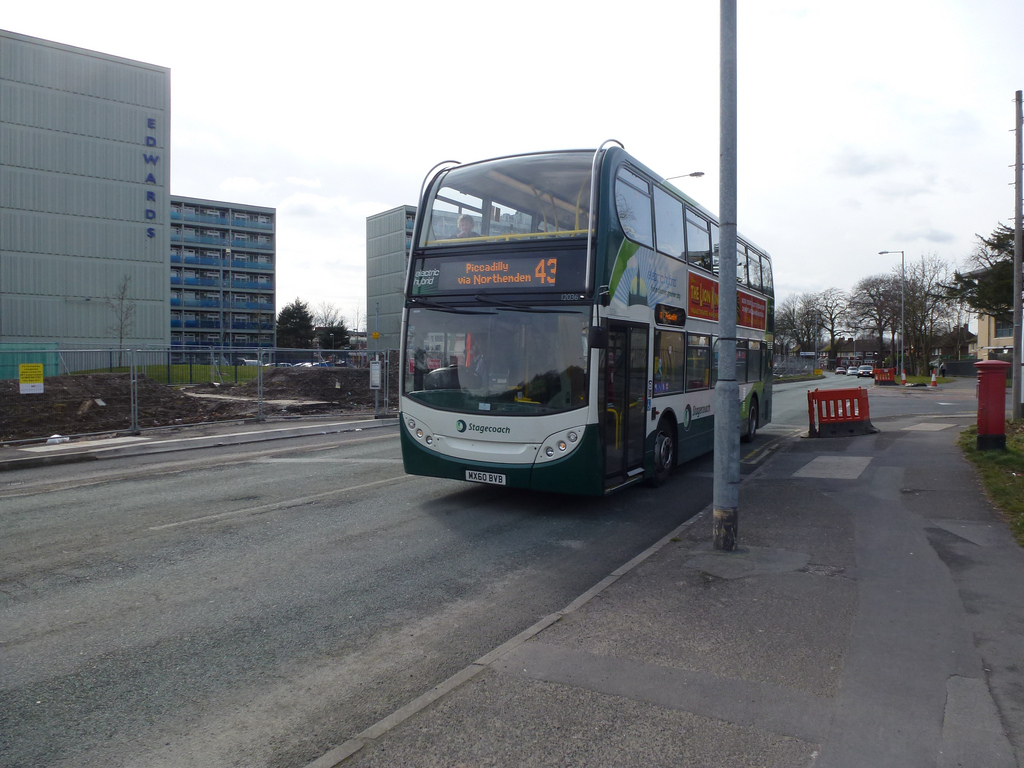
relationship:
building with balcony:
[172, 196, 277, 378] [179, 243, 224, 259]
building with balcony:
[172, 196, 277, 378] [232, 231, 278, 244]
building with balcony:
[172, 196, 277, 378] [175, 227, 229, 248]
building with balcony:
[172, 196, 277, 378] [229, 209, 278, 226]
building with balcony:
[172, 196, 277, 378] [178, 203, 224, 219]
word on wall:
[137, 105, 164, 252] [0, 35, 174, 390]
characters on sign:
[443, 254, 558, 289] [436, 260, 556, 291]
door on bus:
[603, 315, 649, 480] [403, 129, 787, 512]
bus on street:
[403, 129, 787, 512] [144, 405, 600, 693]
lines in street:
[135, 457, 411, 531] [143, 405, 598, 693]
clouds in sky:
[206, 16, 701, 128] [0, 11, 992, 327]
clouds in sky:
[748, 133, 1001, 247] [0, 7, 992, 373]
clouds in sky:
[736, 24, 1015, 250] [0, 11, 992, 327]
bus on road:
[403, 129, 787, 512] [157, 500, 358, 678]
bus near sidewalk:
[403, 129, 787, 512] [740, 626, 868, 750]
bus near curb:
[403, 129, 787, 512] [571, 567, 656, 676]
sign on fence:
[17, 362, 45, 395] [53, 371, 138, 436]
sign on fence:
[10, 343, 56, 400] [12, 353, 48, 399]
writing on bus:
[450, 417, 514, 440] [425, 138, 791, 558]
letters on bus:
[451, 416, 516, 440] [437, 150, 814, 542]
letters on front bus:
[463, 417, 515, 441] [403, 105, 793, 572]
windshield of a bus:
[396, 299, 605, 417] [412, 150, 741, 485]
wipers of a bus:
[405, 290, 593, 306] [384, 126, 771, 501]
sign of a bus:
[434, 255, 565, 294] [368, 139, 798, 490]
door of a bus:
[593, 322, 641, 479] [368, 139, 798, 490]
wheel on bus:
[643, 411, 691, 478] [368, 139, 798, 490]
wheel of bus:
[735, 386, 770, 432] [378, 145, 799, 525]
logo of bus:
[446, 414, 522, 447] [368, 139, 798, 490]